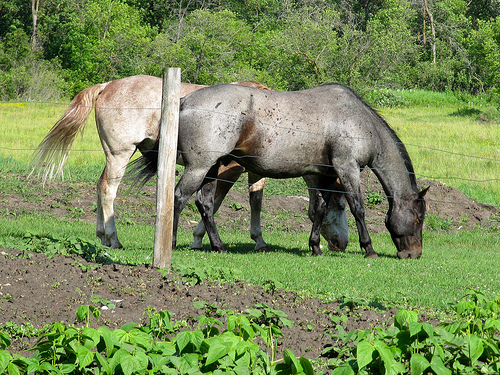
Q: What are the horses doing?
A: Eating.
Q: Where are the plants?
A: In the soil.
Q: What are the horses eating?
A: Grass.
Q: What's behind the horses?
A: Trees.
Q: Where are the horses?
A: In a pin.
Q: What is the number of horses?
A: 2.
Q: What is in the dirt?
A: Crops.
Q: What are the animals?
A: Horses.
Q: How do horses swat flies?
A: With their tails.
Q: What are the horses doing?
A: Grazing.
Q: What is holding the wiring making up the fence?
A: Wood post.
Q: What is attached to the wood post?
A: Wire.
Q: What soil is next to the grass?
A: Dirt.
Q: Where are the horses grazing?
A: Grass field.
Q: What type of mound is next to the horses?
A: Dirt mound.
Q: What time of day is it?
A: Daytime.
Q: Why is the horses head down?
A: Eating.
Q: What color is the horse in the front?
A: Gray.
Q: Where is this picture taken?
A: Farm.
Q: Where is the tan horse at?
A: Back.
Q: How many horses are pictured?
A: Two.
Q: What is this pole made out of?
A: Wood.